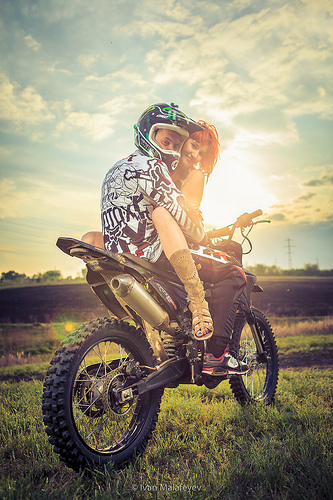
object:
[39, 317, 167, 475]
tire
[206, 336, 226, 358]
sock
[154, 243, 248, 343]
pants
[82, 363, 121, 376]
chain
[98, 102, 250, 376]
man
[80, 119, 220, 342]
girl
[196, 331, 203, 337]
toenail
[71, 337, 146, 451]
wheel spokes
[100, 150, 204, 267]
shirt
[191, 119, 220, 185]
hair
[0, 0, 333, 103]
clouds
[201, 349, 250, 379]
black shoe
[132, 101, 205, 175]
helmet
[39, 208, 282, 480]
motorbike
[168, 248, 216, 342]
boot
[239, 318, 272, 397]
spokes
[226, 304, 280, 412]
wheel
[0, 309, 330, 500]
grass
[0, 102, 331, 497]
foreground